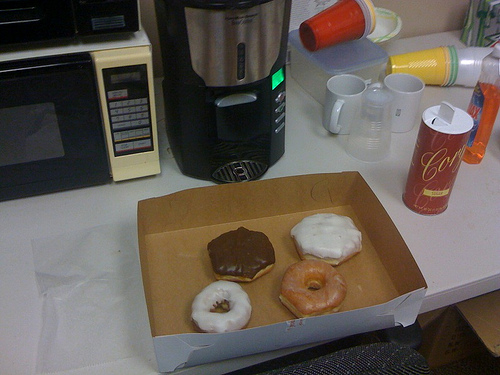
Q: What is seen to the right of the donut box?
A: Creamer container.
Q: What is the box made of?
A: Cardboard.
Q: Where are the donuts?
A: In the box.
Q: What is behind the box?
A: A coffee maker.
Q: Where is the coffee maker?
A: On the table.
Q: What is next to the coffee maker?
A: A microwave.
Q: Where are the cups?
A: To the right of the coffee maker.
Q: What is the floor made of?
A: Carpet.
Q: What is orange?
A: The bottle of dish soap.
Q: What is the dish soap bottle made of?
A: Plastic.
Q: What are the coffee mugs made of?
A: Porcelain.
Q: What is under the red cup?
A: Tupperware dish.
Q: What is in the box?
A: Four donuts.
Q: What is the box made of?
A: Cardboard.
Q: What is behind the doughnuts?
A: Coffee maker.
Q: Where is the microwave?
A: Next to the coffee maker.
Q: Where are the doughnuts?
A: In the box.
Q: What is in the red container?
A: Sugar.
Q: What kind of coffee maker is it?
A: Single cup.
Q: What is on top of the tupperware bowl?
A: Empty cups.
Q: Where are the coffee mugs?
A: On the counter.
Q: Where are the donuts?
A: In the box.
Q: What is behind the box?
A: A coffee maker.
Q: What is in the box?
A: Donuts.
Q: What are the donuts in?
A: The box.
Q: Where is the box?
A: On the counter.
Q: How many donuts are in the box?
A: Four.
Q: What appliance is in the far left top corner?
A: Microwave.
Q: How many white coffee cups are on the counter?
A: Two.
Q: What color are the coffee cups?
A: White.